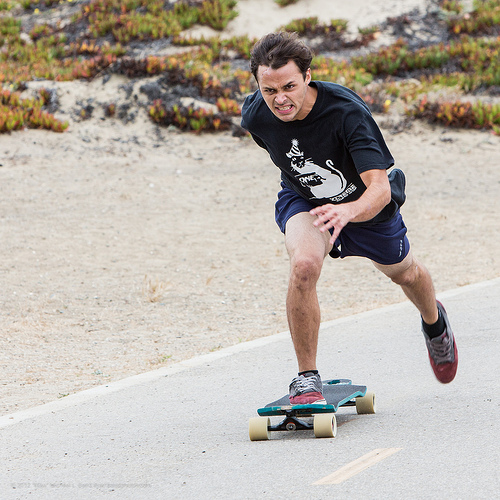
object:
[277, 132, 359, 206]
logo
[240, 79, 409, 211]
shirt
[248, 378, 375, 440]
board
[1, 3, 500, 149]
grass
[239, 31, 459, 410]
man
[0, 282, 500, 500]
road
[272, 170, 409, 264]
shorts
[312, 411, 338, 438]
tires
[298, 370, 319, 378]
socks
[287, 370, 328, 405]
shoes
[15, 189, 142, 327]
dirt